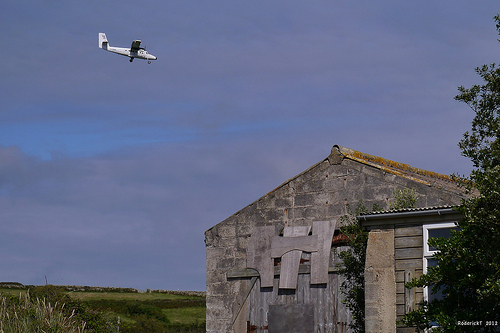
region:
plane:
[90, 22, 170, 69]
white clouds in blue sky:
[9, 3, 45, 60]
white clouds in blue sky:
[219, 73, 253, 112]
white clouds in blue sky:
[332, 55, 372, 105]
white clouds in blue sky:
[152, 121, 192, 175]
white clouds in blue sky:
[113, 215, 138, 247]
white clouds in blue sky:
[6, 111, 64, 161]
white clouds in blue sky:
[58, 185, 111, 258]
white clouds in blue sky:
[335, 63, 390, 121]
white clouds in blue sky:
[259, 22, 319, 68]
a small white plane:
[93, 29, 158, 64]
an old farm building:
[190, 143, 497, 331]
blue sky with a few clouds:
[3, 3, 496, 300]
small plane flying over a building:
[84, 18, 499, 331]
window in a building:
[418, 220, 475, 325]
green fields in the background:
[3, 279, 205, 331]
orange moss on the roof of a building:
[332, 142, 482, 190]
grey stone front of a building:
[199, 149, 476, 331]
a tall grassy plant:
[2, 286, 89, 331]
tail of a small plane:
[96, 28, 109, 48]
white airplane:
[86, 28, 157, 60]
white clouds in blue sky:
[57, 62, 110, 112]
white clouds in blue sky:
[70, 127, 134, 180]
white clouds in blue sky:
[52, 146, 91, 192]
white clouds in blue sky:
[150, 159, 214, 219]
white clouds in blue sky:
[72, 227, 129, 257]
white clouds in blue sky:
[254, 16, 287, 35]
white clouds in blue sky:
[323, 18, 405, 80]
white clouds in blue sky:
[198, 50, 289, 96]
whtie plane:
[80, 26, 161, 68]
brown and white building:
[213, 143, 455, 318]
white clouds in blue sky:
[14, 68, 59, 115]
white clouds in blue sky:
[67, 86, 141, 146]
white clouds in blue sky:
[29, 140, 74, 174]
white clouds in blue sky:
[100, 108, 167, 173]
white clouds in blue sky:
[44, 203, 102, 238]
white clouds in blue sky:
[99, 155, 180, 233]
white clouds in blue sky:
[216, 29, 244, 76]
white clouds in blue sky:
[276, 73, 333, 127]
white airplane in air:
[92, 26, 169, 67]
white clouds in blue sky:
[20, 19, 45, 52]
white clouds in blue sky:
[227, 9, 272, 53]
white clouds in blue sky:
[331, 52, 382, 85]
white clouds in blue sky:
[220, 109, 264, 137]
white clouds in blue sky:
[138, 202, 173, 225]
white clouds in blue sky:
[62, 253, 122, 285]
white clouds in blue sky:
[116, 216, 161, 250]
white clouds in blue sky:
[341, 84, 385, 114]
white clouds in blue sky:
[281, 37, 327, 100]